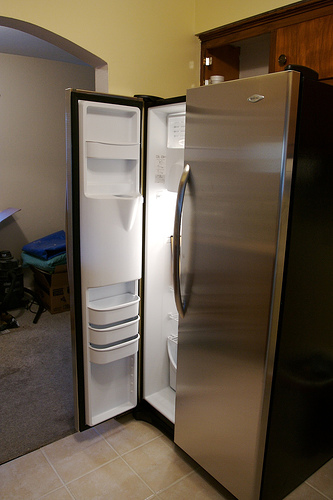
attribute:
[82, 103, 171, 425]
interior — white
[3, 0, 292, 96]
wall — cream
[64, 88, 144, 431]
door — open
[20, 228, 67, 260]
blanket — green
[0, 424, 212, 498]
floor — tiled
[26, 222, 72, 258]
blanket — blue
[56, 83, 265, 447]
door — silver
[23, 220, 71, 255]
blue blanket — green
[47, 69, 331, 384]
fridge — grey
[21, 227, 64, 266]
blanket — on top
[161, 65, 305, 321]
door — steel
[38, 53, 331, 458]
refrigerator — open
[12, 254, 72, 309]
box — cardboard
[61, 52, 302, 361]
fridge — wooden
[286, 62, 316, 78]
black hinge — plastic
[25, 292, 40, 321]
hose — black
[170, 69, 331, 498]
fridge — black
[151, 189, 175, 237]
light — inside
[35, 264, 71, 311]
box — cardboard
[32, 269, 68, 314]
box — brown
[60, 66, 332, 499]
refrigerator — silver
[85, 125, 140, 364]
rack — white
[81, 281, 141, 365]
shelves — white